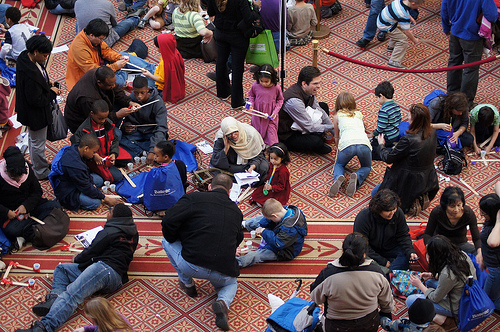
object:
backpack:
[444, 266, 497, 331]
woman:
[211, 114, 271, 188]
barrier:
[307, 37, 321, 100]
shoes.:
[326, 173, 359, 197]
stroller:
[264, 279, 325, 332]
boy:
[371, 82, 404, 162]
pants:
[382, 29, 411, 63]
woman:
[420, 185, 483, 268]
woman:
[309, 232, 396, 331]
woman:
[403, 233, 497, 332]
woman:
[474, 193, 499, 315]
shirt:
[159, 190, 245, 277]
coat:
[160, 187, 245, 280]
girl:
[243, 64, 283, 147]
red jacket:
[157, 33, 186, 101]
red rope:
[320, 46, 498, 74]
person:
[353, 189, 418, 269]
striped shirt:
[171, 7, 205, 39]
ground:
[131, 291, 158, 313]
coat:
[209, 129, 268, 172]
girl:
[328, 91, 373, 198]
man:
[278, 64, 330, 153]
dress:
[243, 83, 283, 145]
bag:
[243, 29, 282, 70]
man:
[12, 203, 137, 332]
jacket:
[75, 220, 141, 281]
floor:
[36, 44, 396, 323]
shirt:
[374, 0, 411, 31]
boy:
[375, 0, 422, 68]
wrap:
[214, 117, 265, 167]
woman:
[209, 0, 256, 107]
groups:
[55, 61, 499, 332]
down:
[67, 66, 135, 141]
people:
[0, 0, 500, 332]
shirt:
[372, 101, 402, 141]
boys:
[143, 33, 186, 103]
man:
[159, 173, 245, 330]